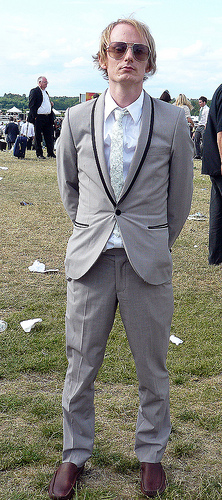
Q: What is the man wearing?
A: A suit.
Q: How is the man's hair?
A: Messy.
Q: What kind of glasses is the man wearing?
A: Sunglasses.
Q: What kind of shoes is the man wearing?
A: Slip-ons.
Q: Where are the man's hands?
A: Behind the back.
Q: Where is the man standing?
A: On a field.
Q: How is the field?
A: Littered with garbage.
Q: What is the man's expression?
A: Serious.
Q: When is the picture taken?
A: Day time.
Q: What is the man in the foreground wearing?
A: Suit.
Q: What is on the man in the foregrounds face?
A: Sunglasses.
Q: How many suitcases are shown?
A: One.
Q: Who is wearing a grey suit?
A: The man.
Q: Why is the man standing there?
A: Posing.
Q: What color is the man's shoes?
A: Brown.